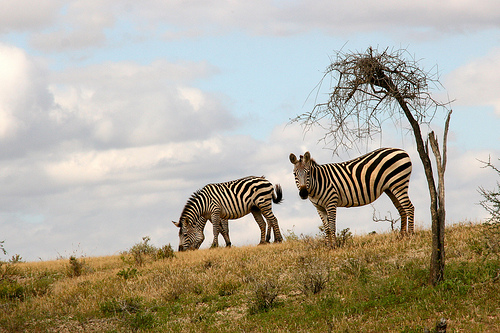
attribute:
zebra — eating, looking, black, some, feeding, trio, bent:
[279, 127, 417, 242]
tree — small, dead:
[341, 43, 461, 294]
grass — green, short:
[318, 276, 397, 324]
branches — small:
[337, 60, 392, 110]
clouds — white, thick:
[86, 66, 179, 148]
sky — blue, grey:
[239, 74, 275, 107]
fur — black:
[188, 197, 204, 210]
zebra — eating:
[169, 161, 278, 254]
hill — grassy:
[45, 237, 144, 302]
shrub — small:
[184, 277, 229, 308]